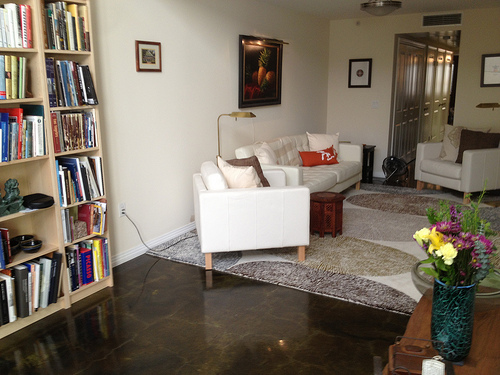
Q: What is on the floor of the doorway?
A: A metal fan.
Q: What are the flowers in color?
A: Yellow and purple.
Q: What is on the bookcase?
A: Books.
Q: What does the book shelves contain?
A: Lots of books.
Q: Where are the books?
A: On wooden bookshelf.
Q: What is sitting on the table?
A: Green vase with flowers.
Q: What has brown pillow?
A: A white chair.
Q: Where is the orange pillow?
A: On a white couch.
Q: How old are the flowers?
A: 3 days old.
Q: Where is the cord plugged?
A: In the wall.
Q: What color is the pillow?
A: Orange.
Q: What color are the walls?
A: White.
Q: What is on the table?
A: A vase with flowers.